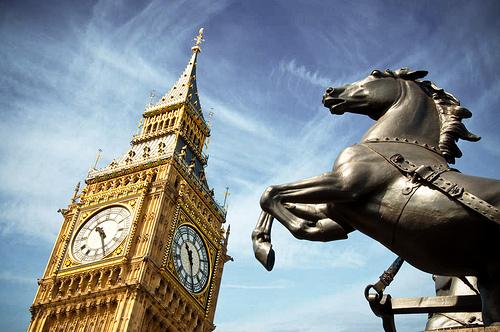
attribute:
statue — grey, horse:
[317, 58, 451, 260]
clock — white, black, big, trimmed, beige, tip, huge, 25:
[55, 208, 118, 262]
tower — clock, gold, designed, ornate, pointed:
[59, 24, 205, 322]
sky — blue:
[271, 30, 277, 33]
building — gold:
[121, 215, 191, 258]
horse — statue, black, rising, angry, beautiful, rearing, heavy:
[257, 44, 486, 300]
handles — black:
[91, 222, 106, 241]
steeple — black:
[177, 155, 214, 178]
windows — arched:
[110, 267, 171, 315]